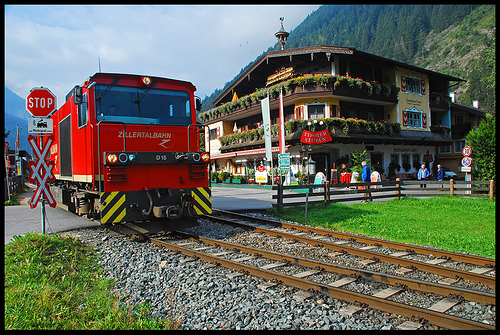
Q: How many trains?
A: 1.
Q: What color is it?
A: Red.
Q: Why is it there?
A: To load.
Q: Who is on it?
A: People.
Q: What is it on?
A: Track.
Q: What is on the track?
A: Train.